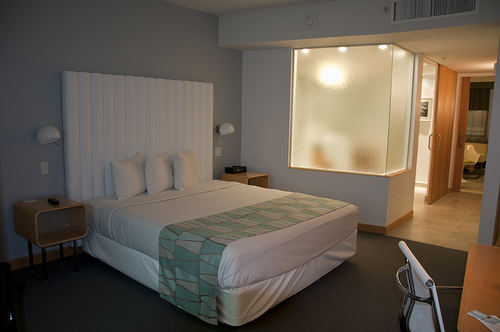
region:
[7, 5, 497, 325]
a clean bathroom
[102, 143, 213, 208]
three white pillows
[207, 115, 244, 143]
a lamp on right side of bed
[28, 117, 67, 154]
lamp on left side of bed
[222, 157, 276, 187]
a night table on right side of bed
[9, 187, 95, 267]
a night table on left side of bed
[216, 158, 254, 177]
a black stuff over a table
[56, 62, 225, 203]
headboard of bed is white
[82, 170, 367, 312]
sheets of bed are white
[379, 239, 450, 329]
a white chair in front a table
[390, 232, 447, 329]
a chair at a desk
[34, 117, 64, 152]
a lamp on a wall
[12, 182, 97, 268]
a nightstand next to a bed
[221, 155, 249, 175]
an alarm clock on a nightstand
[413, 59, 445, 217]
an open bathroom door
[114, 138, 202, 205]
three pillow on a bed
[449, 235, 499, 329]
a brown wooden desk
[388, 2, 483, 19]
a vent next to the ceiling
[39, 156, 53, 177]
a lightswitch next to a bed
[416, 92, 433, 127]
a picture on a wall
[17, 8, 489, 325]
an attractive hotel room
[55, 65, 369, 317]
a king sized bed with modern bedding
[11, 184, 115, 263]
a modern night stand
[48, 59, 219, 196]
a cushioned headboard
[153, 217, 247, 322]
a green and grey bedspread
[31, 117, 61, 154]
rounded white light fixtures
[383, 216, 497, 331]
a chair at a desk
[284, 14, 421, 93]
lighting in an adjacent room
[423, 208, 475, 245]
tan tiled flooring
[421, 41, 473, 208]
brown woodend doors with handles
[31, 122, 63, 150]
built-in bedside lights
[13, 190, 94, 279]
wooden,modern night stand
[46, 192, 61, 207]
remote control for tv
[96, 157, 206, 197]
group of three pillows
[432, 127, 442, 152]
polished metal door handle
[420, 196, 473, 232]
ceramic tile flooring material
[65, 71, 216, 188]
tall white modern head board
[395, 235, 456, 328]
white leather office chair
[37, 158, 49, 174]
wall switch for light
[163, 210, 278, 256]
colorful throw blanket on bed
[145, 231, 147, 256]
side of a bed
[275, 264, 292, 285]
edge of a bed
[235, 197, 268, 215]
part of a mattress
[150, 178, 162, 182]
part of a pillow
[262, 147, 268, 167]
part of a wall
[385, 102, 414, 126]
part of a window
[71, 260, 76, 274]
part of a floor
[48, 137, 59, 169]
part of a bulb